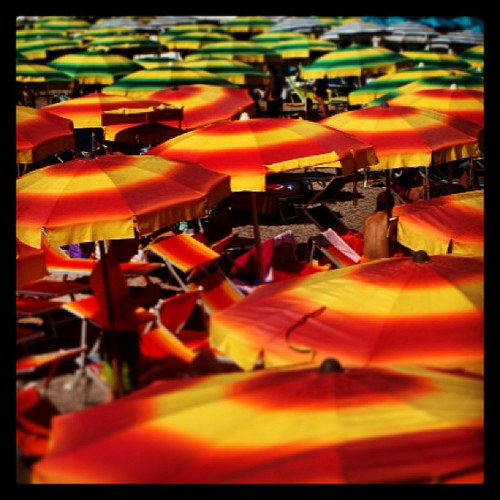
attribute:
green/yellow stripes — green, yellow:
[83, 52, 263, 84]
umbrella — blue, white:
[392, 21, 443, 45]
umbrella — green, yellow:
[123, 62, 230, 91]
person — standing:
[90, 237, 165, 395]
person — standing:
[360, 186, 401, 257]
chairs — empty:
[292, 197, 359, 249]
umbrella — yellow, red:
[194, 245, 497, 379]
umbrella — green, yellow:
[202, 233, 496, 438]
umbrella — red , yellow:
[22, 150, 237, 425]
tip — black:
[316, 358, 343, 378]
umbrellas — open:
[43, 52, 475, 322]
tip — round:
[237, 111, 250, 122]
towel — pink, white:
[265, 227, 298, 282]